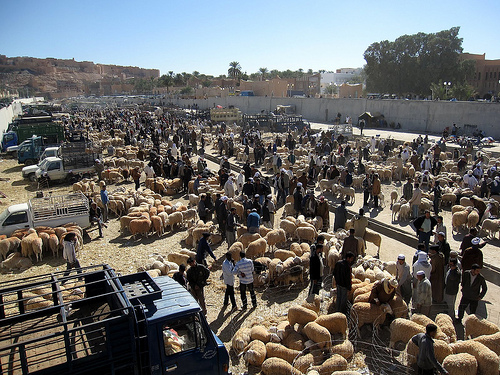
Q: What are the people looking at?
A: Sheep market.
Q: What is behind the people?
A: Gray wall.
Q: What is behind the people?
A: Mountain.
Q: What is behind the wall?
A: Trees.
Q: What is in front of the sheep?
A: Blue truck.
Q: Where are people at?
A: Sheep auction.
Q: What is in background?
A: Concrete wall.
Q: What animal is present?
A: Sheep.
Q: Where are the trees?
A: In far distance.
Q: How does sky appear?
A: Clear and blue.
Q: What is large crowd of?
A: The people.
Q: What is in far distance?
A: Mountains.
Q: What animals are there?
A: Sheep.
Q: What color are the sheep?
A: Tan.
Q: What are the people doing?
A: Standing.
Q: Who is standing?
A: The people.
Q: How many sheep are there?
A: Dozens.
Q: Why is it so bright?
A: Sunny.